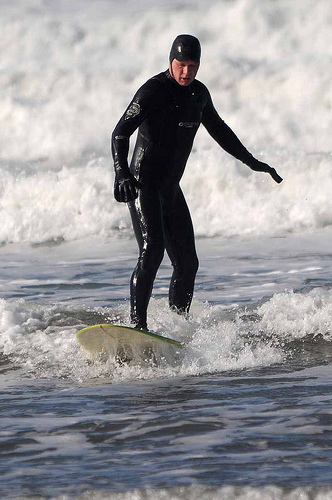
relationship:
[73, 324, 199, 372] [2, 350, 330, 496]
surf board in water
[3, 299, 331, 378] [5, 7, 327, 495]
waves in ocean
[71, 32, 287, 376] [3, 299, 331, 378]
surfing on waves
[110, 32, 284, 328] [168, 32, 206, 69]
man in hat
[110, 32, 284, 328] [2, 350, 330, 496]
man in water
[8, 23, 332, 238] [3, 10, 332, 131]
waves in background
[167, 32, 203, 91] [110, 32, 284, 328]
head of man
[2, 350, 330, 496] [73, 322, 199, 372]
water around surf board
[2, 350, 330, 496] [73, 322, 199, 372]
water in front surf board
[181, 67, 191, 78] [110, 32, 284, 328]
nose of man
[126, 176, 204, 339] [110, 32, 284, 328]
legs of man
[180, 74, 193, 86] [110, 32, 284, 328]
lips of man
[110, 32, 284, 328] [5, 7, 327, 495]
man in ocean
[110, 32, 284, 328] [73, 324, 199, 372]
man on surf board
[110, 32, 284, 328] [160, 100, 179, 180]
man in black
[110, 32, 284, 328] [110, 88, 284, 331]
man wears wet suit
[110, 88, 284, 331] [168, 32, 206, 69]
wet suit has hood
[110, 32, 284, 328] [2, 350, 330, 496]
man watches water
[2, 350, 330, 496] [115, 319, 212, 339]
water at feet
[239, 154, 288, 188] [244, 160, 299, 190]
gloves on hand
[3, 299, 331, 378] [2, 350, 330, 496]
waves in water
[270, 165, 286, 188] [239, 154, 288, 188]
fingers on glove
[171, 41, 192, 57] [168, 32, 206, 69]
label on cap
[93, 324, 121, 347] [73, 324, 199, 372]
line on surf board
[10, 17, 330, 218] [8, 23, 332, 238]
large section of waves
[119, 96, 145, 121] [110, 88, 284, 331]
symbol on wet suit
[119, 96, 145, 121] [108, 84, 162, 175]
symbol on arm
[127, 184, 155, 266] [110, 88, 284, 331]
shine on wet suit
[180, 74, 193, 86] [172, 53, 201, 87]
lips on face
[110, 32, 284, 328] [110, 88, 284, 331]
man in wet suit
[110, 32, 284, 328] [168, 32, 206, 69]
man wearing cap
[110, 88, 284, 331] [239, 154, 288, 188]
wet suit has gloves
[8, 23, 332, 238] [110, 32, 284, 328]
waves behind man